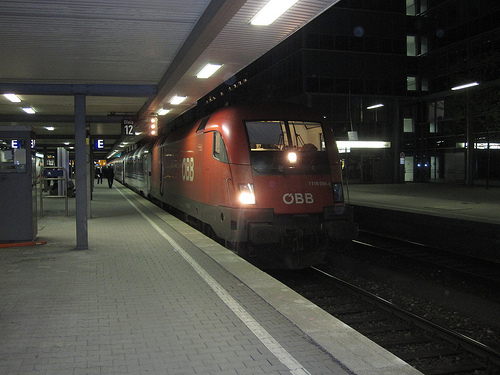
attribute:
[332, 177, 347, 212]
headlight — off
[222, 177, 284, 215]
light — on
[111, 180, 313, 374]
line — white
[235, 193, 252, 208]
light — bright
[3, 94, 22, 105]
light — on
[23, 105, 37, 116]
light — on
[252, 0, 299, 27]
light — on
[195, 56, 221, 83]
light — on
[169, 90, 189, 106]
light — on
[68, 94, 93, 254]
pole — blue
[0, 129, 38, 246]
partition — blue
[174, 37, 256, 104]
light — on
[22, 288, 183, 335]
brick — white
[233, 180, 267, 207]
headlight — on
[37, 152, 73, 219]
gate — silver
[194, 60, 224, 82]
light — on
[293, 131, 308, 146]
wiper — black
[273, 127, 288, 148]
wiper — black